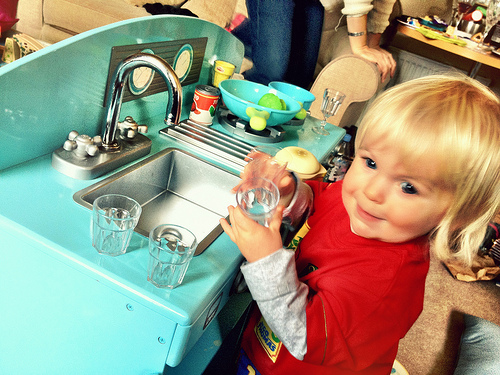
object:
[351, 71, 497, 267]
hair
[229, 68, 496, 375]
boy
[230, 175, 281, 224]
glass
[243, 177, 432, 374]
tshirt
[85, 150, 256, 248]
sink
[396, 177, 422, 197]
eye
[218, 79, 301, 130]
bowl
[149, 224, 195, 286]
glass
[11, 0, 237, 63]
love seat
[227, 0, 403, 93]
woman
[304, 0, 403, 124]
seat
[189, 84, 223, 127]
can of vegetables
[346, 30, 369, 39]
bracelet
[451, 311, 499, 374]
pillow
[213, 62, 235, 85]
cup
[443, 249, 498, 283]
trash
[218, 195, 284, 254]
hand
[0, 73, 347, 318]
surface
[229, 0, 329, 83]
jeans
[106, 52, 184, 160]
faucet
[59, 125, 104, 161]
knob